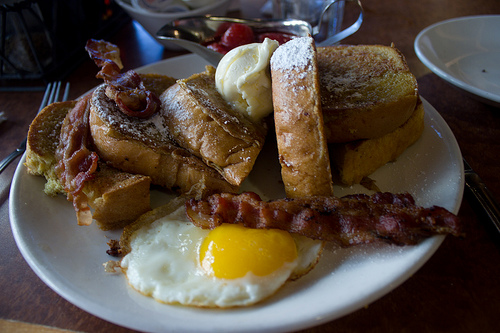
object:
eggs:
[115, 201, 303, 309]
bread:
[311, 43, 419, 141]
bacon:
[185, 190, 466, 249]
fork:
[0, 80, 74, 204]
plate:
[7, 47, 465, 332]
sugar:
[270, 37, 317, 70]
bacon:
[83, 39, 161, 118]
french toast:
[22, 99, 154, 231]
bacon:
[52, 90, 100, 196]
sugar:
[152, 110, 168, 136]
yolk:
[197, 223, 299, 277]